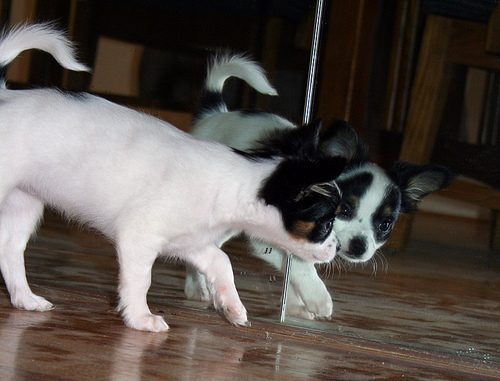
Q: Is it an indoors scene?
A: Yes, it is indoors.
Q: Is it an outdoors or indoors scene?
A: It is indoors.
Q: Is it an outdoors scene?
A: No, it is indoors.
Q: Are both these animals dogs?
A: Yes, all the animals are dogs.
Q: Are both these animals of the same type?
A: Yes, all the animals are dogs.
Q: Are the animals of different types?
A: No, all the animals are dogs.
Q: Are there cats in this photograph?
A: No, there are no cats.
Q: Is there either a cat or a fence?
A: No, there are no cats or fences.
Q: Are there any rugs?
A: No, there are no rugs.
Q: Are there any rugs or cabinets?
A: No, there are no rugs or cabinets.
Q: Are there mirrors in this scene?
A: Yes, there is a mirror.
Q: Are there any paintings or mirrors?
A: Yes, there is a mirror.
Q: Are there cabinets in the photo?
A: No, there are no cabinets.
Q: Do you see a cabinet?
A: No, there are no cabinets.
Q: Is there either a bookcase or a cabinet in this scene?
A: No, there are no cabinets or bookcases.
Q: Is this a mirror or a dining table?
A: This is a mirror.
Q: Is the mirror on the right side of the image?
A: Yes, the mirror is on the right of the image.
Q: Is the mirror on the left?
A: No, the mirror is on the right of the image.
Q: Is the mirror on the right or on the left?
A: The mirror is on the right of the image.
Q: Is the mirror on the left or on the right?
A: The mirror is on the right of the image.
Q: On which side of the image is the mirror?
A: The mirror is on the right of the image.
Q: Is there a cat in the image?
A: No, there are no cats.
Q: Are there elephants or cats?
A: No, there are no cats or elephants.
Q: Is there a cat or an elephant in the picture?
A: No, there are no cats or elephants.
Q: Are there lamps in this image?
A: No, there are no lamps.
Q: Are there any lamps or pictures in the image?
A: No, there are no lamps or pictures.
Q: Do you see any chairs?
A: Yes, there is a chair.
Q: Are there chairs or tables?
A: Yes, there is a chair.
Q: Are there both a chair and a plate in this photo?
A: No, there is a chair but no plates.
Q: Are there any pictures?
A: No, there are no pictures.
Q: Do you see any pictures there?
A: No, there are no pictures.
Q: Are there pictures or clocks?
A: No, there are no pictures or clocks.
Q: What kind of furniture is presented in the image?
A: The furniture is a chair.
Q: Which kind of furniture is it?
A: The piece of furniture is a chair.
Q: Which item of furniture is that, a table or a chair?
A: That is a chair.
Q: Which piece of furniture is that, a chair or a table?
A: That is a chair.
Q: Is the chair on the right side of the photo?
A: Yes, the chair is on the right of the image.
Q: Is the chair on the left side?
A: No, the chair is on the right of the image.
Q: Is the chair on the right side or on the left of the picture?
A: The chair is on the right of the image.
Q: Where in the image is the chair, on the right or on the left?
A: The chair is on the right of the image.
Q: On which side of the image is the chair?
A: The chair is on the right of the image.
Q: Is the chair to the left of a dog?
A: No, the chair is to the right of a dog.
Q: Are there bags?
A: No, there are no bags.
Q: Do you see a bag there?
A: No, there are no bags.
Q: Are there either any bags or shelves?
A: No, there are no bags or shelves.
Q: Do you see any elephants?
A: No, there are no elephants.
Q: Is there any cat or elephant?
A: No, there are no elephants or cats.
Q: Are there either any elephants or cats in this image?
A: No, there are no elephants or cats.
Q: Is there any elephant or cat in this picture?
A: No, there are no elephants or cats.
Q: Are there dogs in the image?
A: Yes, there is a dog.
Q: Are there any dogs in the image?
A: Yes, there is a dog.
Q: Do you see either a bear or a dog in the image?
A: Yes, there is a dog.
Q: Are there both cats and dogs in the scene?
A: No, there is a dog but no cats.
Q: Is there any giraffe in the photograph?
A: No, there are no giraffes.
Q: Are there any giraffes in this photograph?
A: No, there are no giraffes.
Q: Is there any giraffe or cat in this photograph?
A: No, there are no giraffes or cats.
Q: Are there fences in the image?
A: No, there are no fences.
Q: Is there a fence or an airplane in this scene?
A: No, there are no fences or airplanes.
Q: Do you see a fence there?
A: No, there are no fences.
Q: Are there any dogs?
A: Yes, there is a dog.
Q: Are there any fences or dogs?
A: Yes, there is a dog.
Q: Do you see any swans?
A: No, there are no swans.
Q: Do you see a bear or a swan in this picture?
A: No, there are no swans or bears.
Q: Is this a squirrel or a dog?
A: This is a dog.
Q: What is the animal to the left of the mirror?
A: The animal is a dog.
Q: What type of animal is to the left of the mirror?
A: The animal is a dog.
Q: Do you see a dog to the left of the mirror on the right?
A: Yes, there is a dog to the left of the mirror.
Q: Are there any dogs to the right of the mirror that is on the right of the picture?
A: No, the dog is to the left of the mirror.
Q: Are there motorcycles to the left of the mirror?
A: No, there is a dog to the left of the mirror.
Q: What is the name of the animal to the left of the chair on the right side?
A: The animal is a dog.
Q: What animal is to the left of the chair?
A: The animal is a dog.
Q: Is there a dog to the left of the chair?
A: Yes, there is a dog to the left of the chair.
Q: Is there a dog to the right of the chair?
A: No, the dog is to the left of the chair.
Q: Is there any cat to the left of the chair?
A: No, there is a dog to the left of the chair.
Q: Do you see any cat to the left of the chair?
A: No, there is a dog to the left of the chair.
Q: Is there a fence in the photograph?
A: No, there are no fences.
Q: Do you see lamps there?
A: No, there are no lamps.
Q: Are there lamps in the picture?
A: No, there are no lamps.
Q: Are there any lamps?
A: No, there are no lamps.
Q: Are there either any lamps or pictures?
A: No, there are no lamps or pictures.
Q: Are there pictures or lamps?
A: No, there are no lamps or pictures.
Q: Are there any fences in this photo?
A: No, there are no fences.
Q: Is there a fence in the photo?
A: No, there are no fences.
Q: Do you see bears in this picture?
A: No, there are no bears.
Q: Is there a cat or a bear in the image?
A: No, there are no bears or cats.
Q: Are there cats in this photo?
A: No, there are no cats.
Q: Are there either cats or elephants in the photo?
A: No, there are no cats or elephants.